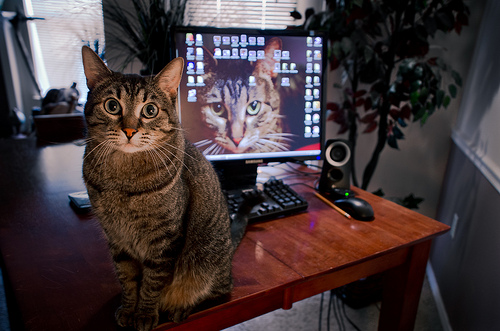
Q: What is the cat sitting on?
A: A desk.